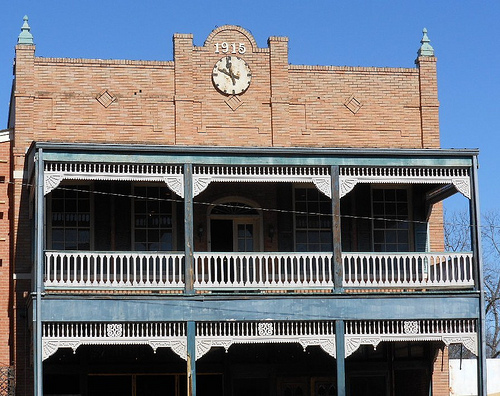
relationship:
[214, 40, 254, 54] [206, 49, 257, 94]
numbers on clock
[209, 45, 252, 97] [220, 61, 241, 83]
clock has hands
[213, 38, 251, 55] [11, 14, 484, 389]
numbers on building